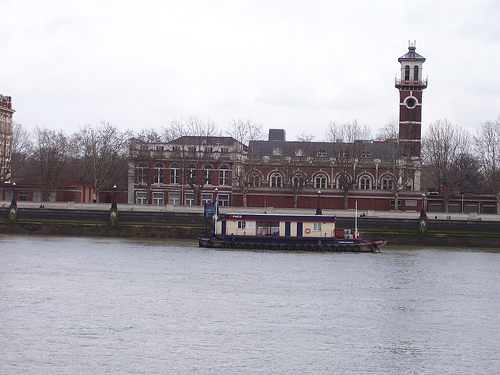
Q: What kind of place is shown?
A: It is a river.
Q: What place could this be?
A: It is a river.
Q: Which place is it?
A: It is a river.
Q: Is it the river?
A: Yes, it is the river.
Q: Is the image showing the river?
A: Yes, it is showing the river.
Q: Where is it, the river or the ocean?
A: It is the river.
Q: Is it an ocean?
A: No, it is a river.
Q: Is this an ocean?
A: No, it is a river.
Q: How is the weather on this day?
A: It is cloudy.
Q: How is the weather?
A: It is cloudy.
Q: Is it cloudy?
A: Yes, it is cloudy.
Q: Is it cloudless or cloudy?
A: It is cloudy.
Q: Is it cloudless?
A: No, it is cloudy.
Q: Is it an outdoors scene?
A: Yes, it is outdoors.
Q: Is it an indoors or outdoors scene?
A: It is outdoors.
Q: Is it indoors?
A: No, it is outdoors.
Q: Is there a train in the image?
A: Yes, there is a train.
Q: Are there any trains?
A: Yes, there is a train.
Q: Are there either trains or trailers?
A: Yes, there is a train.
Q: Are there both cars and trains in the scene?
A: No, there is a train but no cars.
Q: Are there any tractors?
A: No, there are no tractors.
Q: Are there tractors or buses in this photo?
A: No, there are no tractors or buses.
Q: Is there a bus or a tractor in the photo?
A: No, there are no tractors or buses.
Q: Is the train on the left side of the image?
A: Yes, the train is on the left of the image.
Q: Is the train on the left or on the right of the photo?
A: The train is on the left of the image.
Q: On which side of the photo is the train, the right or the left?
A: The train is on the left of the image.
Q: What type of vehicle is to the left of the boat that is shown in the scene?
A: The vehicle is a train.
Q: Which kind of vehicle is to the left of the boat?
A: The vehicle is a train.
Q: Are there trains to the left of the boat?
A: Yes, there is a train to the left of the boat.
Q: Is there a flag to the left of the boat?
A: No, there is a train to the left of the boat.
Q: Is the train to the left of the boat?
A: Yes, the train is to the left of the boat.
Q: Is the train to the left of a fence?
A: No, the train is to the left of the boat.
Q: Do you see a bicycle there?
A: No, there are no bicycles.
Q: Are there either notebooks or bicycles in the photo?
A: No, there are no bicycles or notebooks.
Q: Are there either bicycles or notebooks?
A: No, there are no bicycles or notebooks.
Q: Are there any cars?
A: No, there are no cars.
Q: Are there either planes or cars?
A: No, there are no cars or planes.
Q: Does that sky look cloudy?
A: Yes, the sky is cloudy.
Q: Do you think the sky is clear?
A: No, the sky is cloudy.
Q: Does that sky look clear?
A: No, the sky is cloudy.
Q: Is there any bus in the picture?
A: No, there are no buses.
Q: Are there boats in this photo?
A: Yes, there is a boat.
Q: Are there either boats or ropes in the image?
A: Yes, there is a boat.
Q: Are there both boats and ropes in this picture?
A: No, there is a boat but no ropes.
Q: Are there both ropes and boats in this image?
A: No, there is a boat but no ropes.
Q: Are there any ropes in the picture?
A: No, there are no ropes.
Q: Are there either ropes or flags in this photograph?
A: No, there are no ropes or flags.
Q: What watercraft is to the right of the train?
A: The watercraft is a boat.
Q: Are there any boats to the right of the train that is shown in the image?
A: Yes, there is a boat to the right of the train.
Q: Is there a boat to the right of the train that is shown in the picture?
A: Yes, there is a boat to the right of the train.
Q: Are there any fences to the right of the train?
A: No, there is a boat to the right of the train.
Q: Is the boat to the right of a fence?
A: No, the boat is to the right of a train.